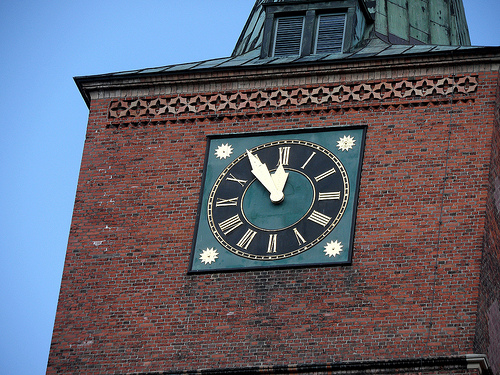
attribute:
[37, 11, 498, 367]
tower — brick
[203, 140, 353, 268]
clock — blue, black, roman, silver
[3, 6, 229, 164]
sky — clear, blue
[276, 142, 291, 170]
numeral — 12, roman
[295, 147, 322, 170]
numeral — 1, roman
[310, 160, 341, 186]
numeral — 2, roman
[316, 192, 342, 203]
numeral — 3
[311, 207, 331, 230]
numeral — roman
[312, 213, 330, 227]
numeral — four, roman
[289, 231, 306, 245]
five — roman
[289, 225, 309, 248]
numeral — five, roman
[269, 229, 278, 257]
numeral — six, roman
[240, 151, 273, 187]
hand — long, white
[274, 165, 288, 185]
hand — small, white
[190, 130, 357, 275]
frame — black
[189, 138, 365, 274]
background — green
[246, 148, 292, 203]
hands — white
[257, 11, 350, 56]
windows — small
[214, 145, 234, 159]
flower — decoration, white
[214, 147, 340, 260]
numerals — roman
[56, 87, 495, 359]
building — brick, red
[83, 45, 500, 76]
roof — green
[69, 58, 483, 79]
ledge — thin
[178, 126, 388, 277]
border — black